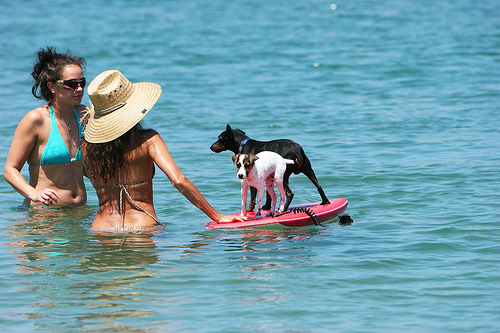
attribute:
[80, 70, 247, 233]
person — swimming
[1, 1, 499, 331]
water — calm, shallow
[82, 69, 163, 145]
hat — straw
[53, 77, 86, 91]
sunglasses — shading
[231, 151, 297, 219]
dog — swimming, white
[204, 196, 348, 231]
surfboard — red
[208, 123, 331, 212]
dog — black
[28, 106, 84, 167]
bikini top — turquoise, blue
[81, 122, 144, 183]
hair — down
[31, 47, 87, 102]
hair — bun